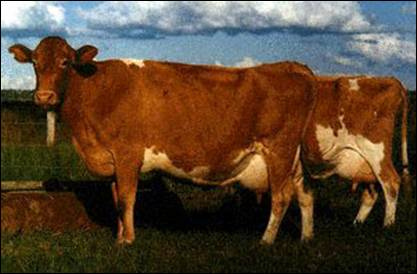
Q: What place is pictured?
A: It is a pasture.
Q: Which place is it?
A: It is a pasture.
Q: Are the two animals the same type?
A: Yes, all the animals are cows.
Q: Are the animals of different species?
A: No, all the animals are cows.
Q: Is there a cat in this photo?
A: No, there are no cats.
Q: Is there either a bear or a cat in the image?
A: No, there are no cats or bears.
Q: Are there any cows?
A: Yes, there is a cow.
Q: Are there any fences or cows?
A: Yes, there is a cow.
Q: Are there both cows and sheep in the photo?
A: No, there is a cow but no sheep.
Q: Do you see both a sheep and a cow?
A: No, there is a cow but no sheep.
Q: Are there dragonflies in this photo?
A: No, there are no dragonflies.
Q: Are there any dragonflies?
A: No, there are no dragonflies.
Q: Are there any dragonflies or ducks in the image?
A: No, there are no dragonflies or ducks.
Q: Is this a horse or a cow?
A: This is a cow.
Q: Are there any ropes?
A: No, there are no ropes.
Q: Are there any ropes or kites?
A: No, there are no ropes or kites.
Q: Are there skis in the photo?
A: No, there are no skis.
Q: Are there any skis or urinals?
A: No, there are no skis or urinals.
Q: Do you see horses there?
A: No, there are no horses.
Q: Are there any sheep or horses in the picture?
A: No, there are no horses or sheep.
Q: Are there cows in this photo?
A: Yes, there is a cow.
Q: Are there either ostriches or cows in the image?
A: Yes, there is a cow.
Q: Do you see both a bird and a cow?
A: No, there is a cow but no birds.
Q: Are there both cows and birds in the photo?
A: No, there is a cow but no birds.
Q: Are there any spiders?
A: No, there are no spiders.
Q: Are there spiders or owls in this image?
A: No, there are no spiders or owls.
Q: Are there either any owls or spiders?
A: No, there are no spiders or owls.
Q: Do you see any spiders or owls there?
A: No, there are no spiders or owls.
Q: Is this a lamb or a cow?
A: This is a cow.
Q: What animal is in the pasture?
A: The cow is in the pasture.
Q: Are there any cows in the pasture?
A: Yes, there is a cow in the pasture.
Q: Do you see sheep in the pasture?
A: No, there is a cow in the pasture.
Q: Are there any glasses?
A: No, there are no glasses.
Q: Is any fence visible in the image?
A: Yes, there is a fence.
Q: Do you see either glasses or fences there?
A: Yes, there is a fence.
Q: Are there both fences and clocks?
A: No, there is a fence but no clocks.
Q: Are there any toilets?
A: No, there are no toilets.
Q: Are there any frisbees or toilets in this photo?
A: No, there are no toilets or frisbees.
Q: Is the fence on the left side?
A: Yes, the fence is on the left of the image.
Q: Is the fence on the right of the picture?
A: No, the fence is on the left of the image.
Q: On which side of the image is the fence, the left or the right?
A: The fence is on the left of the image.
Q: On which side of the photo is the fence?
A: The fence is on the left of the image.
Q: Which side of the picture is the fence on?
A: The fence is on the left of the image.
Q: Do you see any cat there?
A: No, there are no cats.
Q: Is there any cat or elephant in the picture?
A: No, there are no cats or elephants.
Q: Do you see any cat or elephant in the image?
A: No, there are no cats or elephants.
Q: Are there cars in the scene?
A: No, there are no cars.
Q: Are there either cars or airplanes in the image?
A: No, there are no cars or airplanes.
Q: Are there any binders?
A: No, there are no binders.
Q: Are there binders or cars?
A: No, there are no binders or cars.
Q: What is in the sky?
A: The clouds are in the sky.